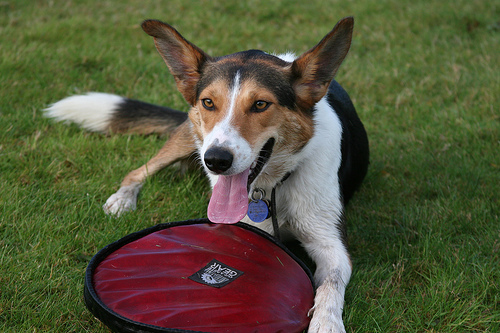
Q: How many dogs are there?
A: One.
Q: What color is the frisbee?
A: Black and red.